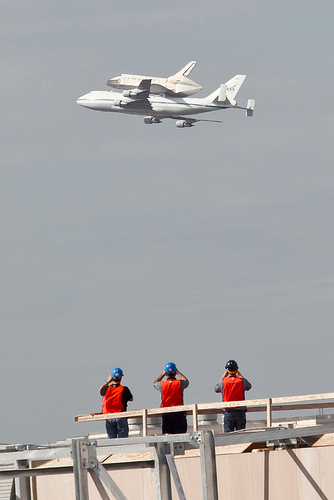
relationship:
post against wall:
[193, 432, 220, 496] [7, 428, 331, 500]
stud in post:
[198, 433, 203, 440] [193, 432, 220, 496]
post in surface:
[193, 432, 220, 496] [7, 428, 331, 500]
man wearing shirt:
[154, 360, 190, 433] [159, 380, 183, 407]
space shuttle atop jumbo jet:
[109, 58, 203, 96] [77, 74, 259, 128]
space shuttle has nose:
[109, 58, 203, 96] [108, 75, 120, 88]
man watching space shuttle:
[154, 360, 190, 433] [109, 58, 203, 96]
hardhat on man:
[224, 358, 240, 375] [215, 360, 254, 432]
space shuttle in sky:
[109, 58, 203, 96] [2, 1, 333, 445]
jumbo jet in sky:
[77, 74, 259, 128] [2, 1, 333, 445]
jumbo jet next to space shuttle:
[77, 74, 259, 128] [109, 58, 203, 96]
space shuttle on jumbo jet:
[109, 58, 203, 96] [77, 74, 259, 128]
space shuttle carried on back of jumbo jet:
[109, 58, 203, 96] [77, 74, 259, 128]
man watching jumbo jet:
[215, 360, 254, 432] [77, 74, 259, 128]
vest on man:
[101, 386, 126, 416] [99, 366, 135, 441]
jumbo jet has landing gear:
[77, 74, 259, 128] [146, 106, 187, 122]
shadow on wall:
[275, 441, 329, 499] [7, 428, 331, 500]